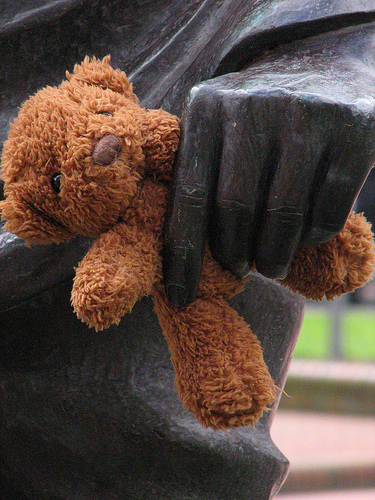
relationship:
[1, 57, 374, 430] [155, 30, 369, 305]
teddy bear in hand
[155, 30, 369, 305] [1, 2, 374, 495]
hand belongs to statue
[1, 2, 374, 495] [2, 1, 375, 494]
statue on left side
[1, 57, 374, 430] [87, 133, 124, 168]
teddy bear has nose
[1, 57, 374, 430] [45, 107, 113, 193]
teddy bear has eyes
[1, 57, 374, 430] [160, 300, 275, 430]
teddy bear has right leg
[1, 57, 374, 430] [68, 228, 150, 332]
teddy bear has right arm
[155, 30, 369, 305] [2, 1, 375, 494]
hand on left side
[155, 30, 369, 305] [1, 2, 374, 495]
hand on statue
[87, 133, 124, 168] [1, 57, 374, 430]
nose on teddy bear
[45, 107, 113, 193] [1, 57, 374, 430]
eyes on teddy bear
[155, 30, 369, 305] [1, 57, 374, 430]
hand holding teddy bear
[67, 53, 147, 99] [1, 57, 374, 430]
ear on teddy bear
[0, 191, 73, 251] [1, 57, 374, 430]
ear on teddy bear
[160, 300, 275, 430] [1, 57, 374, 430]
leg on teddy bear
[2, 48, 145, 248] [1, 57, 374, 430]
head on teddy bear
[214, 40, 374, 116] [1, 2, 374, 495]
reflection on sculpture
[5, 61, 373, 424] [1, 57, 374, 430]
fur on toy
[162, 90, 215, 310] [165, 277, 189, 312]
finger has nail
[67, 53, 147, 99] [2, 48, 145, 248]
ear on head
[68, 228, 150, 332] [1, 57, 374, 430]
arm on teddy bear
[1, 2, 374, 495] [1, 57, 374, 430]
statue holding teddy bear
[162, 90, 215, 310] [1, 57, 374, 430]
finger touching teddy bear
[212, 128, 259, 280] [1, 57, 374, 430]
finger touching teddy bear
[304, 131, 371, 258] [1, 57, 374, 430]
pinky holding teddy bear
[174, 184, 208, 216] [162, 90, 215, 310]
wrinkle on finger